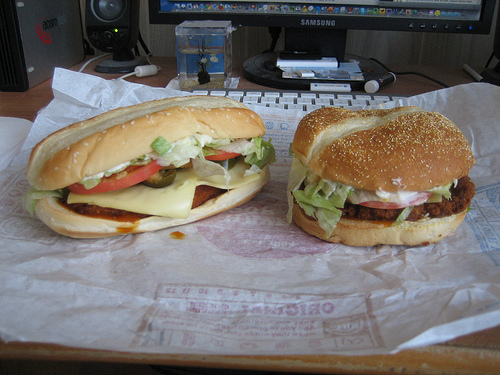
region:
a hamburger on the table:
[283, 95, 481, 259]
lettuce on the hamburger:
[286, 159, 341, 236]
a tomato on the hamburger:
[366, 200, 431, 208]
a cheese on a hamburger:
[74, 189, 194, 220]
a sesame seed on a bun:
[118, 122, 128, 129]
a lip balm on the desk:
[364, 70, 398, 97]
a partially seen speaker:
[82, 0, 148, 76]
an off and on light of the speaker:
[112, 26, 119, 33]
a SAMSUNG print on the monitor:
[297, 16, 339, 28]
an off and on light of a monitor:
[466, 23, 473, 31]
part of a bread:
[417, 129, 431, 146]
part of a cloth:
[242, 272, 277, 331]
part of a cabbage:
[311, 192, 335, 242]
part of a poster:
[269, 285, 298, 314]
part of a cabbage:
[301, 192, 337, 301]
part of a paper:
[241, 238, 272, 277]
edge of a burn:
[365, 218, 392, 232]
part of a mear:
[372, 198, 419, 260]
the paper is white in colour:
[196, 231, 373, 354]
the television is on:
[206, 0, 486, 33]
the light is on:
[104, 0, 129, 53]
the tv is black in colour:
[235, 7, 485, 28]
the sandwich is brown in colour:
[54, 103, 286, 243]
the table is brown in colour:
[14, 81, 72, 113]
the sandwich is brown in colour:
[331, 190, 451, 226]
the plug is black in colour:
[263, 20, 289, 53]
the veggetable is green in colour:
[283, 146, 343, 233]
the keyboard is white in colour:
[236, 78, 311, 120]